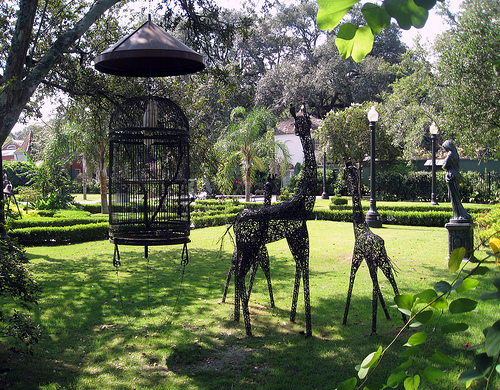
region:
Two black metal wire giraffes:
[216, 100, 415, 353]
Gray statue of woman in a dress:
[437, 137, 477, 280]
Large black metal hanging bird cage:
[84, 8, 205, 354]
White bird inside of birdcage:
[132, 93, 175, 155]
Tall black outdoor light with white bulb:
[362, 104, 389, 231]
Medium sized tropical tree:
[210, 96, 290, 204]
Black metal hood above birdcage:
[83, 13, 215, 93]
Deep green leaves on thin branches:
[329, 197, 499, 387]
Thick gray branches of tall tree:
[2, 2, 110, 162]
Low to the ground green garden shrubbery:
[12, 206, 105, 251]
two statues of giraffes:
[214, 80, 395, 339]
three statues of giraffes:
[194, 110, 400, 342]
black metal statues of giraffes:
[208, 106, 397, 353]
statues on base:
[427, 135, 483, 266]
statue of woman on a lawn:
[427, 142, 479, 279]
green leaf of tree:
[320, 13, 382, 68]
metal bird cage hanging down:
[97, 102, 189, 249]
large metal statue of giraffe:
[228, 103, 326, 335]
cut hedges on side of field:
[15, 215, 91, 243]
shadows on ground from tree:
[25, 302, 122, 374]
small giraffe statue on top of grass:
[341, 156, 409, 335]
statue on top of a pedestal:
[441, 137, 473, 222]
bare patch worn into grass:
[176, 342, 251, 374]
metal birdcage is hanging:
[108, 96, 193, 243]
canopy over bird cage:
[93, 20, 206, 76]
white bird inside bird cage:
[142, 100, 162, 147]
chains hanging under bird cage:
[111, 243, 194, 337]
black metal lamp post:
[367, 123, 381, 228]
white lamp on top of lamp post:
[368, 109, 378, 121]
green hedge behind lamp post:
[315, 206, 351, 223]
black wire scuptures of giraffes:
[209, 97, 400, 345]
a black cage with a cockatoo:
[109, 87, 191, 279]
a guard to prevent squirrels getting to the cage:
[91, 19, 202, 78]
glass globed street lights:
[364, 103, 439, 208]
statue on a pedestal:
[438, 139, 469, 261]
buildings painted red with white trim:
[5, 144, 100, 181]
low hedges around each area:
[11, 203, 286, 253]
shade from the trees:
[28, 239, 386, 389]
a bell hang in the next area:
[1, 178, 28, 234]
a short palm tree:
[217, 108, 288, 199]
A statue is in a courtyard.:
[434, 133, 487, 271]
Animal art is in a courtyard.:
[220, 110, 405, 315]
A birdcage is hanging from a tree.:
[98, 3, 210, 280]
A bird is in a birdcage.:
[103, 96, 218, 262]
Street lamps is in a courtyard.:
[361, 103, 443, 220]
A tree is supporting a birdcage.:
[65, 35, 241, 257]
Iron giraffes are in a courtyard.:
[221, 103, 410, 343]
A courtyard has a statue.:
[433, 133, 482, 257]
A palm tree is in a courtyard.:
[208, 93, 275, 200]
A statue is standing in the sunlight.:
[400, 114, 481, 286]